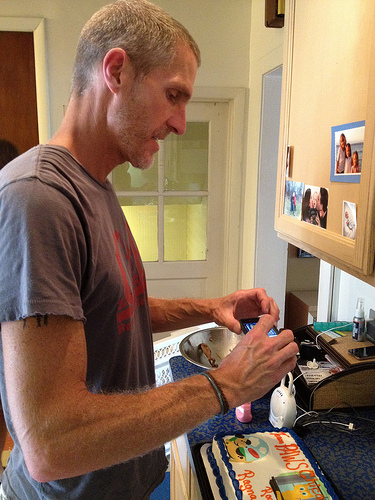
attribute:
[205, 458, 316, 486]
cake — white, decorated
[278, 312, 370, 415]
box — pale, brown, trimmed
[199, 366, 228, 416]
wrist band — black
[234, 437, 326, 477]
icing — blue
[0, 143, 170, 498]
shirt — gray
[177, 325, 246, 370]
bowl — silver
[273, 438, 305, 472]
writing — orange